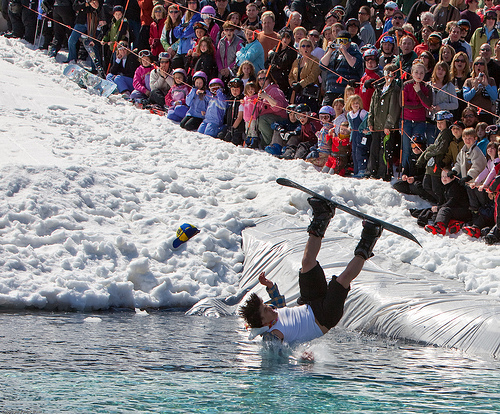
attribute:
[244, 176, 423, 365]
snowboarder — down, falling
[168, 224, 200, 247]
hat — flying, yellow, blue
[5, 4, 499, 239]
audience — watching, shocked, behind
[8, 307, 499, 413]
water — cold, ice, pool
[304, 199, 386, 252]
feet — snowboarder's, man's, elevated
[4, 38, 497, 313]
snow — white, rough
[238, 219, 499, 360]
tarp — white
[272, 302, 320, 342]
shirt — white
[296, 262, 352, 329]
shorts — black, brown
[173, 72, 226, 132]
child — sitting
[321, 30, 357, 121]
man — recording